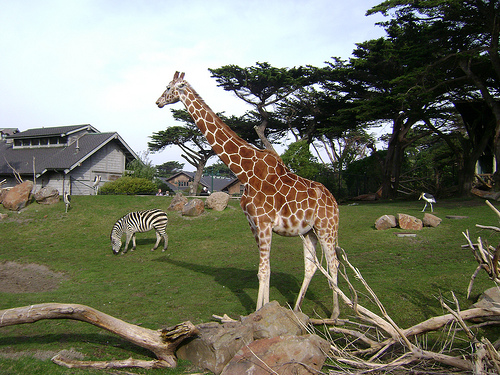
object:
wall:
[69, 139, 124, 195]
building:
[0, 123, 155, 198]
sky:
[0, 0, 499, 174]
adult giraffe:
[154, 71, 344, 324]